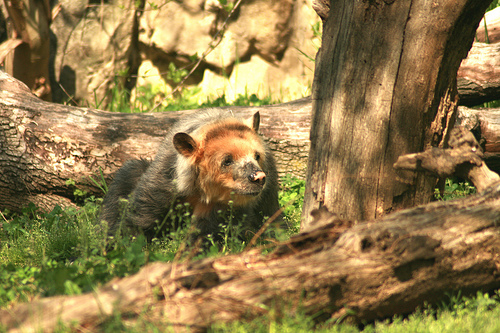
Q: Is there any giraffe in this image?
A: No, there are no giraffes.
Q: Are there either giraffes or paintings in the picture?
A: No, there are no giraffes or paintings.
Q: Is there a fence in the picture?
A: No, there are no fences.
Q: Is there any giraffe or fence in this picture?
A: No, there are no fences or giraffes.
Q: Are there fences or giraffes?
A: No, there are no fences or giraffes.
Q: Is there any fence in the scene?
A: No, there are no fences.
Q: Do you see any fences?
A: No, there are no fences.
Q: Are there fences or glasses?
A: No, there are no fences or glasses.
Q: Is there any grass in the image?
A: Yes, there is grass.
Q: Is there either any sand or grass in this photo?
A: Yes, there is grass.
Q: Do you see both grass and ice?
A: No, there is grass but no ice.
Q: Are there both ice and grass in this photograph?
A: No, there is grass but no ice.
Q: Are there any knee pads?
A: No, there are no knee pads.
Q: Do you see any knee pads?
A: No, there are no knee pads.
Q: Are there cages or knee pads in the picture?
A: No, there are no knee pads or cages.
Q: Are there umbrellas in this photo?
A: No, there are no umbrellas.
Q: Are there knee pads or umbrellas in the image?
A: No, there are no umbrellas or knee pads.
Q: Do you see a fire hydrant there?
A: No, there are no fire hydrants.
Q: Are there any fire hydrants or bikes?
A: No, there are no fire hydrants or bikes.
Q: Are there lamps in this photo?
A: No, there are no lamps.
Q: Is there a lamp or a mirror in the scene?
A: No, there are no lamps or mirrors.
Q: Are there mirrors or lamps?
A: No, there are no lamps or mirrors.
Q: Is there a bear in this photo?
A: Yes, there is a bear.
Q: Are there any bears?
A: Yes, there is a bear.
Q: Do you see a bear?
A: Yes, there is a bear.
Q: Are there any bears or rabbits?
A: Yes, there is a bear.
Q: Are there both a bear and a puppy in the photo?
A: No, there is a bear but no puppies.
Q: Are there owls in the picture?
A: No, there are no owls.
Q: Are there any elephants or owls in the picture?
A: No, there are no owls or elephants.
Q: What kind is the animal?
A: The animal is a bear.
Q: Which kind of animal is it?
A: The animal is a bear.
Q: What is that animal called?
A: This is a bear.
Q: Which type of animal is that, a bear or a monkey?
A: This is a bear.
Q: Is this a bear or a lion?
A: This is a bear.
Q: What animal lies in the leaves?
A: The bear lies in the leaves.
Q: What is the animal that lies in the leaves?
A: The animal is a bear.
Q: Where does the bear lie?
A: The bear lies in the leaves.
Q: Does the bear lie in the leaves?
A: Yes, the bear lies in the leaves.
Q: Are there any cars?
A: No, there are no cars.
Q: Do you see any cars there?
A: No, there are no cars.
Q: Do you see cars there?
A: No, there are no cars.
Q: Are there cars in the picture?
A: No, there are no cars.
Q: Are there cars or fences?
A: No, there are no cars or fences.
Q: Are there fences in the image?
A: No, there are no fences.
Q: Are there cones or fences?
A: No, there are no fences or cones.